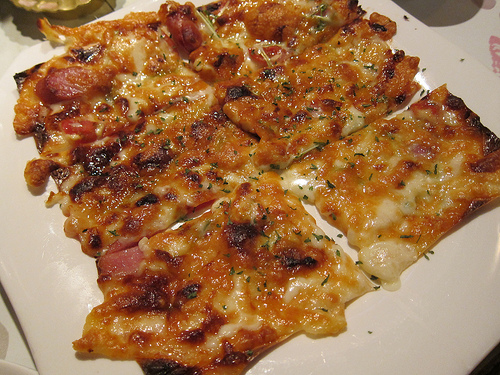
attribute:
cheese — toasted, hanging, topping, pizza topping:
[31, 1, 500, 364]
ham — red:
[43, 2, 221, 300]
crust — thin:
[12, 2, 500, 375]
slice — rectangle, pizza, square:
[95, 153, 377, 366]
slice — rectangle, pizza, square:
[276, 80, 500, 296]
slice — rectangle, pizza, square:
[206, 2, 424, 170]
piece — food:
[64, 81, 262, 250]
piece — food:
[17, 5, 238, 173]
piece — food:
[181, 0, 367, 95]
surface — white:
[1, 0, 498, 368]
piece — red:
[34, 56, 115, 107]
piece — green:
[326, 176, 341, 191]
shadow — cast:
[409, 0, 482, 35]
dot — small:
[365, 326, 377, 337]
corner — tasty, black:
[18, 11, 215, 165]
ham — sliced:
[89, 245, 153, 279]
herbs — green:
[223, 137, 400, 270]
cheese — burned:
[74, 263, 205, 357]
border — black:
[13, 52, 98, 186]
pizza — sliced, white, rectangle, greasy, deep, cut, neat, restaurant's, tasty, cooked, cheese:
[6, 2, 499, 367]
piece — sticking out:
[70, 280, 189, 361]